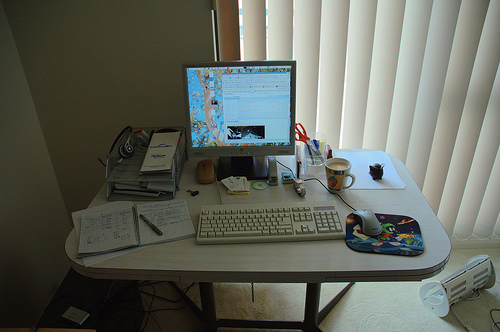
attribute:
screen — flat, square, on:
[182, 62, 293, 155]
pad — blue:
[349, 212, 423, 255]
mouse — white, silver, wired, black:
[352, 207, 382, 236]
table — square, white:
[70, 140, 436, 280]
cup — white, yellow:
[325, 157, 353, 194]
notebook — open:
[77, 199, 193, 248]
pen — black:
[141, 212, 164, 237]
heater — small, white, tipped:
[423, 251, 494, 315]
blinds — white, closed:
[233, 5, 498, 217]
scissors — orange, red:
[292, 122, 321, 159]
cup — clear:
[303, 138, 324, 166]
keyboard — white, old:
[197, 199, 340, 239]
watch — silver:
[292, 176, 306, 197]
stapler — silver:
[267, 155, 280, 188]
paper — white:
[338, 149, 398, 190]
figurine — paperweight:
[365, 162, 387, 181]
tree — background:
[194, 74, 230, 146]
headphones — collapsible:
[119, 129, 137, 161]